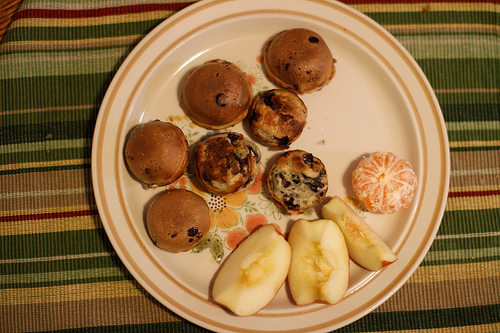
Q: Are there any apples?
A: Yes, there is an apple.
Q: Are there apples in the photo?
A: Yes, there is an apple.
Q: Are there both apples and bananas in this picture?
A: No, there is an apple but no bananas.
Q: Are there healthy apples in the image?
A: Yes, there is a healthy apple.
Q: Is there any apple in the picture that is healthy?
A: Yes, there is an apple that is healthy.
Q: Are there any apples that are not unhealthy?
A: Yes, there is an healthy apple.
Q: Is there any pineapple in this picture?
A: No, there are no pineapples.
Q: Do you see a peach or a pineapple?
A: No, there are no pineapples or peaches.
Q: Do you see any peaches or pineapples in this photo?
A: No, there are no pineapples or peaches.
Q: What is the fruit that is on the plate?
A: The fruit is an apple.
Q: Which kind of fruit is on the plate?
A: The fruit is an apple.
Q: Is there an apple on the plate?
A: Yes, there is an apple on the plate.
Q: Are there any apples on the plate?
A: Yes, there is an apple on the plate.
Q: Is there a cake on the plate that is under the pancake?
A: No, there is an apple on the plate.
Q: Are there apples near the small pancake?
A: Yes, there is an apple near the pancake.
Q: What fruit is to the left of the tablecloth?
A: The fruit is an apple.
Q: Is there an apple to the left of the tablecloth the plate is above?
A: Yes, there is an apple to the left of the tablecloth.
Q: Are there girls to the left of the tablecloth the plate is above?
A: No, there is an apple to the left of the table cloth.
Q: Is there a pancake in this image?
A: Yes, there is a pancake.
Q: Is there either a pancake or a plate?
A: Yes, there is a pancake.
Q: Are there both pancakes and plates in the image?
A: Yes, there are both a pancake and a plate.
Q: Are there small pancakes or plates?
A: Yes, there is a small pancake.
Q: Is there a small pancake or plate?
A: Yes, there is a small pancake.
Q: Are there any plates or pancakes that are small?
A: Yes, the pancake is small.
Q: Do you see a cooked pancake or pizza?
A: Yes, there is a cooked pancake.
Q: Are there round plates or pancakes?
A: Yes, there is a round pancake.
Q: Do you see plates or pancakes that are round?
A: Yes, the pancake is round.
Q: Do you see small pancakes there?
A: Yes, there is a small pancake.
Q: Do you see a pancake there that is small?
A: Yes, there is a pancake that is small.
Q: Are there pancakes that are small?
A: Yes, there is a pancake that is small.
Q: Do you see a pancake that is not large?
A: Yes, there is a small pancake.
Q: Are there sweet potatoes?
A: No, there are no sweet potatoes.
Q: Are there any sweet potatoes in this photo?
A: No, there are no sweet potatoes.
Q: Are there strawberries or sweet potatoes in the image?
A: No, there are no sweet potatoes or strawberries.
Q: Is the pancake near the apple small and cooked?
A: Yes, the pancake is small and cooked.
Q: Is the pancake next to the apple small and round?
A: Yes, the pancake is small and round.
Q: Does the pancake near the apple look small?
A: Yes, the pancake is small.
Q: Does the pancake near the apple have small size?
A: Yes, the pancake is small.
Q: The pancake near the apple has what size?
A: The pancake is small.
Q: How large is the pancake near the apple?
A: The pancake is small.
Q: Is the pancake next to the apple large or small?
A: The pancake is small.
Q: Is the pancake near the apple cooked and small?
A: Yes, the pancake is cooked and small.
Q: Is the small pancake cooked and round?
A: Yes, the pancake is cooked and round.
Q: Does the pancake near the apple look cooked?
A: Yes, the pancake is cooked.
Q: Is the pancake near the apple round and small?
A: Yes, the pancake is round and small.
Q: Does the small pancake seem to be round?
A: Yes, the pancake is round.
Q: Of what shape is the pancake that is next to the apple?
A: The pancake is round.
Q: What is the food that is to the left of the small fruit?
A: The food is a pancake.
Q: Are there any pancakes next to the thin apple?
A: Yes, there is a pancake next to the apple.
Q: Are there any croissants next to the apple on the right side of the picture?
A: No, there is a pancake next to the apple.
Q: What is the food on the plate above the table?
A: The food is a pancake.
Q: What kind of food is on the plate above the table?
A: The food is a pancake.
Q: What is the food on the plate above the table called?
A: The food is a pancake.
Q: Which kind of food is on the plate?
A: The food is a pancake.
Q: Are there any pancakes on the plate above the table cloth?
A: Yes, there is a pancake on the plate.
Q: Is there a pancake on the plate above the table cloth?
A: Yes, there is a pancake on the plate.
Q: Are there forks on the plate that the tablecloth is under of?
A: No, there is a pancake on the plate.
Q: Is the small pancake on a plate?
A: Yes, the pancake is on a plate.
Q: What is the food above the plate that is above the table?
A: The food is a pancake.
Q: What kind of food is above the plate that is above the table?
A: The food is a pancake.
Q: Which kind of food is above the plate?
A: The food is a pancake.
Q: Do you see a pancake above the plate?
A: Yes, there is a pancake above the plate.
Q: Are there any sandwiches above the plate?
A: No, there is a pancake above the plate.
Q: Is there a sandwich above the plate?
A: No, there is a pancake above the plate.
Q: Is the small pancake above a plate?
A: Yes, the pancake is above a plate.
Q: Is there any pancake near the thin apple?
A: Yes, there is a pancake near the apple.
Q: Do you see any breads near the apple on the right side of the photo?
A: No, there is a pancake near the apple.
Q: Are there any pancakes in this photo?
A: Yes, there is a pancake.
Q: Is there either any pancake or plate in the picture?
A: Yes, there is a pancake.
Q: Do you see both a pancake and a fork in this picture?
A: No, there is a pancake but no forks.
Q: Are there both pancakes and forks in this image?
A: No, there is a pancake but no forks.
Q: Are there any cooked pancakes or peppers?
A: Yes, there is a cooked pancake.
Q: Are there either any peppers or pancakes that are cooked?
A: Yes, the pancake is cooked.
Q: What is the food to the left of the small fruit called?
A: The food is a pancake.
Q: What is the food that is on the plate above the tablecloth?
A: The food is a pancake.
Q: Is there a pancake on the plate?
A: Yes, there is a pancake on the plate.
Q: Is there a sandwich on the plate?
A: No, there is a pancake on the plate.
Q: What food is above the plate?
A: The food is a pancake.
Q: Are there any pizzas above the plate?
A: No, there is a pancake above the plate.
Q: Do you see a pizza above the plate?
A: No, there is a pancake above the plate.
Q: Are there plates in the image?
A: Yes, there is a plate.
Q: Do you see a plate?
A: Yes, there is a plate.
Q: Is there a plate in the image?
A: Yes, there is a plate.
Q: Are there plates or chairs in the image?
A: Yes, there is a plate.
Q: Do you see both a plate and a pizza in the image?
A: No, there is a plate but no pizzas.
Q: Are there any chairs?
A: No, there are no chairs.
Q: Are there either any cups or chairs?
A: No, there are no chairs or cups.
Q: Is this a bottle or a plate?
A: This is a plate.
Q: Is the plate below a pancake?
A: Yes, the plate is below a pancake.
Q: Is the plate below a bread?
A: No, the plate is below a pancake.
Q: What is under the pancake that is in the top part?
A: The plate is under the pancake.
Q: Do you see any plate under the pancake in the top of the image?
A: Yes, there is a plate under the pancake.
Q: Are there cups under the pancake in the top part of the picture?
A: No, there is a plate under the pancake.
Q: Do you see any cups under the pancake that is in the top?
A: No, there is a plate under the pancake.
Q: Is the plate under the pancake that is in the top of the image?
A: Yes, the plate is under the pancake.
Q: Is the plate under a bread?
A: No, the plate is under the pancake.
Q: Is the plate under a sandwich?
A: No, the plate is under the pancake.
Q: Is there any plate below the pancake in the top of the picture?
A: Yes, there is a plate below the pancake.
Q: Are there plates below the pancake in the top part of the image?
A: Yes, there is a plate below the pancake.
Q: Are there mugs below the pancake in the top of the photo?
A: No, there is a plate below the pancake.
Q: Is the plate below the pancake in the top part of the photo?
A: Yes, the plate is below the pancake.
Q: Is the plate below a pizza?
A: No, the plate is below the pancake.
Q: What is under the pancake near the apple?
A: The plate is under the pancake.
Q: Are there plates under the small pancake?
A: Yes, there is a plate under the pancake.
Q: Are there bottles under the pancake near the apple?
A: No, there is a plate under the pancake.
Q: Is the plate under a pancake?
A: Yes, the plate is under a pancake.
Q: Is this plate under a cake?
A: No, the plate is under a pancake.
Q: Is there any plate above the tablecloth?
A: Yes, there is a plate above the tablecloth.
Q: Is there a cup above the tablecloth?
A: No, there is a plate above the tablecloth.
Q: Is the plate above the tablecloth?
A: Yes, the plate is above the tablecloth.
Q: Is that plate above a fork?
A: No, the plate is above the tablecloth.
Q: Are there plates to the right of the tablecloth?
A: No, the plate is to the left of the tablecloth.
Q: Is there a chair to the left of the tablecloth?
A: No, there is a plate to the left of the tablecloth.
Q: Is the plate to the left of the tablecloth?
A: Yes, the plate is to the left of the tablecloth.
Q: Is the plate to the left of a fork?
A: No, the plate is to the left of the tablecloth.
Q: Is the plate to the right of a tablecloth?
A: No, the plate is to the left of a tablecloth.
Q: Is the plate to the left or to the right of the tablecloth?
A: The plate is to the left of the tablecloth.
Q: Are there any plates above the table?
A: Yes, there is a plate above the table.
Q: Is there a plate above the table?
A: Yes, there is a plate above the table.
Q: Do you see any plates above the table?
A: Yes, there is a plate above the table.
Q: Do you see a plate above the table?
A: Yes, there is a plate above the table.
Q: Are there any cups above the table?
A: No, there is a plate above the table.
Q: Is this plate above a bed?
A: No, the plate is above the table.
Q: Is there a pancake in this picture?
A: Yes, there is a pancake.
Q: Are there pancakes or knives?
A: Yes, there is a pancake.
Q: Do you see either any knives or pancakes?
A: Yes, there is a pancake.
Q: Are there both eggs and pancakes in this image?
A: No, there is a pancake but no eggs.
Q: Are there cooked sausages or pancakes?
A: Yes, there is a cooked pancake.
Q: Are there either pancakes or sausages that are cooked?
A: Yes, the pancake is cooked.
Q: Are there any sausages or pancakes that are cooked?
A: Yes, the pancake is cooked.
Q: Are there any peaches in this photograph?
A: No, there are no peaches.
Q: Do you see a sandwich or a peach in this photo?
A: No, there are no peaches or sandwiches.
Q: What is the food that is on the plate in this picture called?
A: The food is a pancake.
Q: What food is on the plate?
A: The food is a pancake.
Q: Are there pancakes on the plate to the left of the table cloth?
A: Yes, there is a pancake on the plate.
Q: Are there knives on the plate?
A: No, there is a pancake on the plate.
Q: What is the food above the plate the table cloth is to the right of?
A: The food is a pancake.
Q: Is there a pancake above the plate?
A: Yes, there is a pancake above the plate.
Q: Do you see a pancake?
A: Yes, there is a pancake.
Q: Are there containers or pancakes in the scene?
A: Yes, there is a pancake.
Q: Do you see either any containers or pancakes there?
A: Yes, there is a pancake.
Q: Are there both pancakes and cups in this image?
A: No, there is a pancake but no cups.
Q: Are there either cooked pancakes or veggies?
A: Yes, there is a cooked pancake.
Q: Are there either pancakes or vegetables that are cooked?
A: Yes, the pancake is cooked.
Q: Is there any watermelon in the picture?
A: No, there are no watermelons.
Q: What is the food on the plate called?
A: The food is a pancake.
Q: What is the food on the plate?
A: The food is a pancake.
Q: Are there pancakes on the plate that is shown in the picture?
A: Yes, there is a pancake on the plate.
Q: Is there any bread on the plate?
A: No, there is a pancake on the plate.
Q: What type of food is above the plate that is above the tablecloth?
A: The food is a pancake.